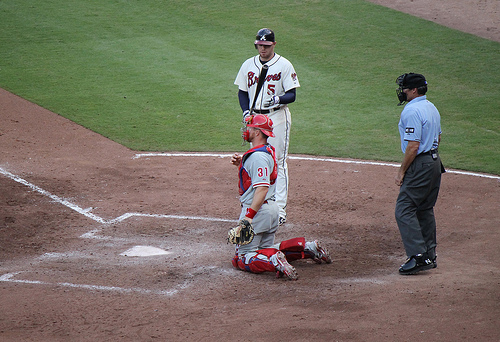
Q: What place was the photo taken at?
A: It was taken at the field.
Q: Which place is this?
A: It is a field.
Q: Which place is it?
A: It is a field.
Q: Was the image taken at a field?
A: Yes, it was taken in a field.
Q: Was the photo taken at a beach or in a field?
A: It was taken at a field.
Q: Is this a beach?
A: No, it is a field.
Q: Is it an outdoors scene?
A: Yes, it is outdoors.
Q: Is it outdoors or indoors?
A: It is outdoors.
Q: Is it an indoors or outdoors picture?
A: It is outdoors.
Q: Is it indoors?
A: No, it is outdoors.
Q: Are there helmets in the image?
A: Yes, there is a helmet.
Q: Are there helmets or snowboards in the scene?
A: Yes, there is a helmet.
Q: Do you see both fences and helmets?
A: No, there is a helmet but no fences.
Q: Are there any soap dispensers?
A: No, there are no soap dispensers.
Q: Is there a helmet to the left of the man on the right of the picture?
A: Yes, there is a helmet to the left of the man.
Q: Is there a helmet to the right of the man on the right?
A: No, the helmet is to the left of the man.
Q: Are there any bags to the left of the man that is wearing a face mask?
A: No, there is a helmet to the left of the man.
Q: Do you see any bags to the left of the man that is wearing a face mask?
A: No, there is a helmet to the left of the man.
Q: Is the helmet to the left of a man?
A: Yes, the helmet is to the left of a man.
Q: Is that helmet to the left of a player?
A: No, the helmet is to the left of a man.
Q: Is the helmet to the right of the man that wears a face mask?
A: No, the helmet is to the left of the man.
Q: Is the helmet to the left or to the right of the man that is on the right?
A: The helmet is to the left of the man.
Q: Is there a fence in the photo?
A: No, there are no fences.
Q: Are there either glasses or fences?
A: No, there are no fences or glasses.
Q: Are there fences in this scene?
A: No, there are no fences.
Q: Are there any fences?
A: No, there are no fences.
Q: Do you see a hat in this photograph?
A: Yes, there is a hat.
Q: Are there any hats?
A: Yes, there is a hat.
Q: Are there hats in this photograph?
A: Yes, there is a hat.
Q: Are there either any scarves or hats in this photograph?
A: Yes, there is a hat.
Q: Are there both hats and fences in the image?
A: No, there is a hat but no fences.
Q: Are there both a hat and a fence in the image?
A: No, there is a hat but no fences.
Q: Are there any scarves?
A: No, there are no scarves.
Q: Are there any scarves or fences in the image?
A: No, there are no scarves or fences.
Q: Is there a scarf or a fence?
A: No, there are no scarves or fences.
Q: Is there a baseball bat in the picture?
A: Yes, there is a baseball bat.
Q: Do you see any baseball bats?
A: Yes, there is a baseball bat.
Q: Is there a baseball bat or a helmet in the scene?
A: Yes, there is a baseball bat.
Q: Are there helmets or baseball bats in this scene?
A: Yes, there is a baseball bat.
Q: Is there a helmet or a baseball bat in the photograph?
A: Yes, there is a baseball bat.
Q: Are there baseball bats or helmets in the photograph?
A: Yes, there is a baseball bat.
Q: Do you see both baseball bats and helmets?
A: Yes, there are both a baseball bat and a helmet.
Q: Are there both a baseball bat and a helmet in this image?
A: Yes, there are both a baseball bat and a helmet.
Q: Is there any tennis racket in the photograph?
A: No, there are no rackets.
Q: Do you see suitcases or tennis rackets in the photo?
A: No, there are no tennis rackets or suitcases.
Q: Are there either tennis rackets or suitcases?
A: No, there are no tennis rackets or suitcases.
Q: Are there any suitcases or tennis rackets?
A: No, there are no tennis rackets or suitcases.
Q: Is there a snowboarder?
A: No, there are no snowboarders.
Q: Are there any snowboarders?
A: No, there are no snowboarders.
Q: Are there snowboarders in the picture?
A: No, there are no snowboarders.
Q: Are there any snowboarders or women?
A: No, there are no snowboarders or women.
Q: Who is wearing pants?
A: The man is wearing pants.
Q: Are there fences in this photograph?
A: No, there are no fences.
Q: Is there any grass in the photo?
A: Yes, there is grass.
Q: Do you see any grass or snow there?
A: Yes, there is grass.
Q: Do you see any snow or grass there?
A: Yes, there is grass.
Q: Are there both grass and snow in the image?
A: No, there is grass but no snow.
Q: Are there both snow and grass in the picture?
A: No, there is grass but no snow.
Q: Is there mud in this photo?
A: No, there is no mud.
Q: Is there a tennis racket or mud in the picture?
A: No, there are no mud or rackets.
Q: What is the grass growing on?
A: The grass is growing on the field.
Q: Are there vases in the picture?
A: No, there are no vases.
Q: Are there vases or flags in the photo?
A: No, there are no vases or flags.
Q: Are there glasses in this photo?
A: No, there are no glasses.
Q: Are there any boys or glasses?
A: No, there are no glasses or boys.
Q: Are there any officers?
A: No, there are no officers.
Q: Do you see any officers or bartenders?
A: No, there are no officers or bartenders.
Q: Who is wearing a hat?
A: The man is wearing a hat.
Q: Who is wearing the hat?
A: The man is wearing a hat.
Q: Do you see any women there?
A: No, there are no women.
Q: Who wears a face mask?
A: The man wears a face mask.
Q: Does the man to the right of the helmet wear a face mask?
A: Yes, the man wears a face mask.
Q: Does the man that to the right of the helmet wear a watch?
A: No, the man wears a face mask.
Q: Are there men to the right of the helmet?
A: Yes, there is a man to the right of the helmet.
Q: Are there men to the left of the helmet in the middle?
A: No, the man is to the right of the helmet.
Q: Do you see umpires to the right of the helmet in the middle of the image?
A: No, there is a man to the right of the helmet.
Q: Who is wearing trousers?
A: The man is wearing trousers.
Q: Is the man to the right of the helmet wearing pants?
A: Yes, the man is wearing pants.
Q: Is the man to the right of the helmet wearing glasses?
A: No, the man is wearing pants.